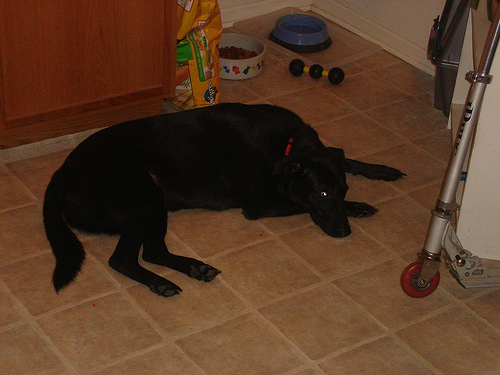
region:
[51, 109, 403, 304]
a dog on the floor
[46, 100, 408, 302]
the dog is black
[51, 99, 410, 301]
the dog lays on the floor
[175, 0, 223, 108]
a bag of dog food on the floor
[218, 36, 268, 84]
a bowl of dog food on the floor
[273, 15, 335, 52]
a bowl of water on the floor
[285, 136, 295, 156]
the dog has red collar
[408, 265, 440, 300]
a scooter has red wheel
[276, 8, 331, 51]
the bowl is blue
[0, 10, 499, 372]
the floor is tiled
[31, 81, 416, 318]
black dog on the floor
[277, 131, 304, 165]
red collar on a dog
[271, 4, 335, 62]
blue water bowl for a dog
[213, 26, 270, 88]
dog food bowl filled with food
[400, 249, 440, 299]
red wheel of a scooter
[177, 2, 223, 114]
bag of dog food by dog food bowls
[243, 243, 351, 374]
tan square tiled floor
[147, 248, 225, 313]
back paws of a black dog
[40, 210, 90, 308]
tail of a black dog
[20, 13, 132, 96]
wooden cabinet door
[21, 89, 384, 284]
the dog is black in color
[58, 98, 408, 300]
the dog is lying on the floor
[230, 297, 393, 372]
the floor is tiled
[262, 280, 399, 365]
the tiles are brown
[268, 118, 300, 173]
the colar is red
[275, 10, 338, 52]
the dog has a blue plate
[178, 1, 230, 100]
the bag food is yellow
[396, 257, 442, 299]
the wheel is red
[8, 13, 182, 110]
the cabinet is brown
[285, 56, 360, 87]
the toy is black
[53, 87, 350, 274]
black dog on tile floor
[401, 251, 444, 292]
red wheel on walker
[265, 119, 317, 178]
red collar on black dog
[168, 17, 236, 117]
yellow bag of dog food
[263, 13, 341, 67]
blue dog dish on the floor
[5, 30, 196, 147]
wood cabinets on left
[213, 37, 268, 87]
large white dog dish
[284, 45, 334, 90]
small toy on tile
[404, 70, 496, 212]
silver scooter on left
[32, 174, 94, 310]
dog's fluffy tail on tile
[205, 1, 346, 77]
food and water bowl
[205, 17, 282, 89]
dog food in bowl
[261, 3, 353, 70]
water in dog's bowl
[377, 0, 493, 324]
shiny grey scooter in front of dog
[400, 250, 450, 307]
red front wheel of scooter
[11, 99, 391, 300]
black dog laying on floor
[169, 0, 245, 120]
bag of dog food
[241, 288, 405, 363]
tan tile on floor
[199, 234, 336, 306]
tan tile on floor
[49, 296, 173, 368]
tan tile on floor